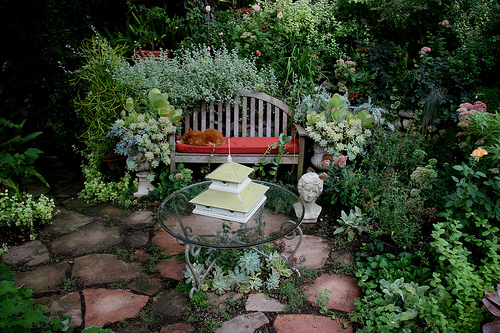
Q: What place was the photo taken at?
A: It was taken at the garden.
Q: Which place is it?
A: It is a garden.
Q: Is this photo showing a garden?
A: Yes, it is showing a garden.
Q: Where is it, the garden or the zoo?
A: It is the garden.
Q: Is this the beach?
A: No, it is the garden.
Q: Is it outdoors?
A: Yes, it is outdoors.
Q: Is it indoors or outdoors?
A: It is outdoors.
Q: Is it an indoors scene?
A: No, it is outdoors.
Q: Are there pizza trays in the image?
A: No, there are no pizza trays.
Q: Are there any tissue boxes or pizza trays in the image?
A: No, there are no pizza trays or tissue boxes.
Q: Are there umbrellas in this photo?
A: No, there are no umbrellas.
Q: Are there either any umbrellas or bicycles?
A: No, there are no umbrellas or bicycles.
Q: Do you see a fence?
A: No, there are no fences.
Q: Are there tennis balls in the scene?
A: No, there are no tennis balls.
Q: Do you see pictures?
A: No, there are no pictures.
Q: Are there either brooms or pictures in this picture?
A: No, there are no pictures or brooms.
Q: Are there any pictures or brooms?
A: No, there are no pictures or brooms.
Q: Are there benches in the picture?
A: Yes, there is a bench.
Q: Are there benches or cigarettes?
A: Yes, there is a bench.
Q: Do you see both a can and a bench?
A: No, there is a bench but no cans.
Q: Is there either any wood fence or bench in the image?
A: Yes, there is a wood bench.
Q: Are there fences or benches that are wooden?
A: Yes, the bench is wooden.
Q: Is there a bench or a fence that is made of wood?
A: Yes, the bench is made of wood.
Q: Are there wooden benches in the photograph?
A: Yes, there is a wood bench.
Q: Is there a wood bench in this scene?
A: Yes, there is a wood bench.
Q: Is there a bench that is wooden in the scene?
A: Yes, there is a wood bench.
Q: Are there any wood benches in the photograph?
A: Yes, there is a wood bench.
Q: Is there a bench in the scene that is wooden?
A: Yes, there is a bench that is wooden.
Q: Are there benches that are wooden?
A: Yes, there is a bench that is wooden.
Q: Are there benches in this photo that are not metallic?
A: Yes, there is a wooden bench.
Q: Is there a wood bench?
A: Yes, there is a bench that is made of wood.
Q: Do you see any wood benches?
A: Yes, there is a bench that is made of wood.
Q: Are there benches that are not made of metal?
A: Yes, there is a bench that is made of wood.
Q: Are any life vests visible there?
A: No, there are no life vests.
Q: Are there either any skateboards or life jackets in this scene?
A: No, there are no life jackets or skateboards.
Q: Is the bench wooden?
A: Yes, the bench is wooden.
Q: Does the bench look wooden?
A: Yes, the bench is wooden.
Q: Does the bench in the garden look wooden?
A: Yes, the bench is wooden.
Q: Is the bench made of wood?
A: Yes, the bench is made of wood.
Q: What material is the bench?
A: The bench is made of wood.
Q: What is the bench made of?
A: The bench is made of wood.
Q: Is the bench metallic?
A: No, the bench is wooden.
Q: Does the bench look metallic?
A: No, the bench is wooden.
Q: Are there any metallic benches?
A: No, there is a bench but it is wooden.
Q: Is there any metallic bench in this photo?
A: No, there is a bench but it is wooden.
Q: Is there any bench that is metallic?
A: No, there is a bench but it is wooden.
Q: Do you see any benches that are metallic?
A: No, there is a bench but it is wooden.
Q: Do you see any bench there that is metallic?
A: No, there is a bench but it is wooden.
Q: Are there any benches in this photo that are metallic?
A: No, there is a bench but it is wooden.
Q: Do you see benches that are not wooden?
A: No, there is a bench but it is wooden.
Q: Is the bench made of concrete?
A: No, the bench is made of wood.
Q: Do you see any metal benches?
A: No, there is a bench but it is made of wood.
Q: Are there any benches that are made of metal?
A: No, there is a bench but it is made of wood.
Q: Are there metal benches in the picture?
A: No, there is a bench but it is made of wood.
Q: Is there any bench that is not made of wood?
A: No, there is a bench but it is made of wood.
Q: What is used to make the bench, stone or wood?
A: The bench is made of wood.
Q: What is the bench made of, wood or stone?
A: The bench is made of wood.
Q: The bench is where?
A: The bench is in the garden.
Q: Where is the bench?
A: The bench is in the garden.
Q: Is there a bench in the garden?
A: Yes, there is a bench in the garden.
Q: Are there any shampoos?
A: No, there are no shampoos.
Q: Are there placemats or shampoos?
A: No, there are no shampoos or placemats.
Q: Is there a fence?
A: No, there are no fences.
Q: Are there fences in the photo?
A: No, there are no fences.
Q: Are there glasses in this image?
A: No, there are no glasses.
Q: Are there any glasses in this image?
A: No, there are no glasses.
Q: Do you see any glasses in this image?
A: No, there are no glasses.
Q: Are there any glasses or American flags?
A: No, there are no glasses or American flags.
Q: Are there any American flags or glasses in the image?
A: No, there are no glasses or American flags.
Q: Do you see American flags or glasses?
A: No, there are no glasses or American flags.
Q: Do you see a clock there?
A: No, there are no clocks.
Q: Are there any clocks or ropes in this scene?
A: No, there are no clocks or ropes.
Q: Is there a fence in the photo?
A: No, there are no fences.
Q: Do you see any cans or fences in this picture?
A: No, there are no fences or cans.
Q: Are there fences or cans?
A: No, there are no fences or cans.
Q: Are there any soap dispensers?
A: No, there are no soap dispensers.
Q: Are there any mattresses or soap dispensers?
A: No, there are no soap dispensers or mattresses.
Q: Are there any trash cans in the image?
A: No, there are no trash cans.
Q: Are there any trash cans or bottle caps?
A: No, there are no trash cans or bottle caps.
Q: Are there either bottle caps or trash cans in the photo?
A: No, there are no trash cans or bottle caps.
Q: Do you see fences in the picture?
A: No, there are no fences.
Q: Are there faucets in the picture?
A: No, there are no faucets.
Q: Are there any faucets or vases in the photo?
A: No, there are no faucets or vases.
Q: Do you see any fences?
A: No, there are no fences.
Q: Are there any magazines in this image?
A: No, there are no magazines.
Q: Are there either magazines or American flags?
A: No, there are no magazines or American flags.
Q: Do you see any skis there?
A: No, there are no skis.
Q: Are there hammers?
A: No, there are no hammers.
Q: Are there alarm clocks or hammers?
A: No, there are no hammers or alarm clocks.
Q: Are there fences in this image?
A: No, there are no fences.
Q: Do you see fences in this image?
A: No, there are no fences.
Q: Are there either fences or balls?
A: No, there are no fences or balls.